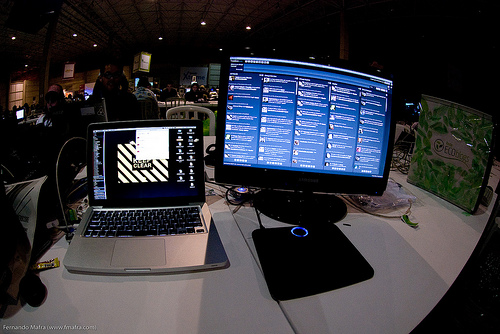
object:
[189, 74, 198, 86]
person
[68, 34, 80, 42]
light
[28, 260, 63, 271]
candy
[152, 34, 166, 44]
lights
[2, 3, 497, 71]
ceiling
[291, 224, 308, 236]
part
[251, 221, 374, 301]
touch pad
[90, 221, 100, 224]
key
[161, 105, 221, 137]
white chair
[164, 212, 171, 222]
key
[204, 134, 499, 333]
table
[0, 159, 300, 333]
table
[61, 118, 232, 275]
laptop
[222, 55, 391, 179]
monitor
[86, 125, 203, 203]
screen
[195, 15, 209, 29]
light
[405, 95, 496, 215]
box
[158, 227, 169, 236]
black key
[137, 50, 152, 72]
poster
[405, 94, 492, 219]
binder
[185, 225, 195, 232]
black key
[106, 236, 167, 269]
track pad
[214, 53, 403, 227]
computer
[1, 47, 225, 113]
wall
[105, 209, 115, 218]
key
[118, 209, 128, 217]
key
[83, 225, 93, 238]
key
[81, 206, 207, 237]
keyboard